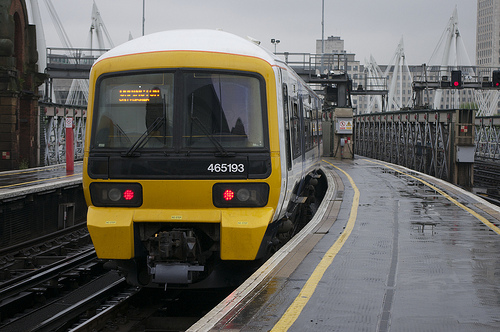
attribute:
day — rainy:
[1, 1, 496, 328]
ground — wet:
[218, 143, 497, 327]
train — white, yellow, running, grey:
[85, 28, 327, 288]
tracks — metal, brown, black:
[5, 219, 189, 330]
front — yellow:
[84, 50, 277, 256]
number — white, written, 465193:
[206, 161, 245, 173]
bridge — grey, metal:
[41, 45, 482, 81]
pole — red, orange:
[64, 114, 73, 174]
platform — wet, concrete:
[0, 155, 82, 197]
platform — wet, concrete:
[233, 149, 494, 332]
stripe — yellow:
[267, 161, 361, 330]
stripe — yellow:
[368, 153, 500, 239]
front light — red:
[213, 181, 269, 207]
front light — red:
[89, 182, 143, 209]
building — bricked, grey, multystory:
[473, 2, 499, 167]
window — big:
[93, 74, 264, 176]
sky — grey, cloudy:
[33, 4, 479, 56]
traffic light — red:
[448, 69, 465, 90]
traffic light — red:
[490, 69, 500, 87]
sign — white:
[65, 117, 76, 129]